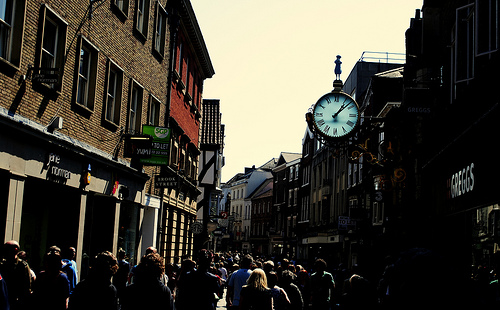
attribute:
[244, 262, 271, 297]
hair. — blonde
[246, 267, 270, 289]
hair — blond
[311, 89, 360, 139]
clock face — black, white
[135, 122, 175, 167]
sign — green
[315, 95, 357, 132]
face — white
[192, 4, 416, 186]
sky — bright, white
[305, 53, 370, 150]
clock — detailed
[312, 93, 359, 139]
clock — large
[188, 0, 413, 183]
white sky — light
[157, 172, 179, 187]
sign — black, white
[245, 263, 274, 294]
hair — blond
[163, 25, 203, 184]
wall — red